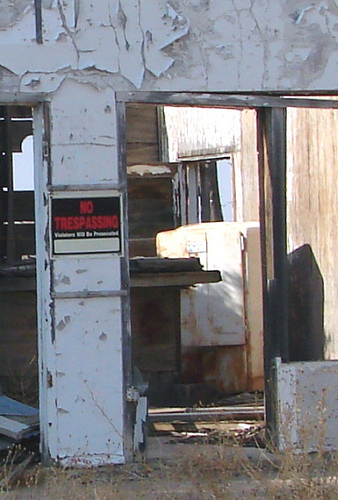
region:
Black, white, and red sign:
[47, 189, 126, 262]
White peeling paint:
[20, 5, 187, 79]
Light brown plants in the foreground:
[15, 407, 321, 499]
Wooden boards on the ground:
[142, 386, 269, 451]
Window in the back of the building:
[168, 138, 244, 244]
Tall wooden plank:
[247, 110, 291, 449]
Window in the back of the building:
[13, 128, 44, 198]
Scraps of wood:
[3, 394, 45, 461]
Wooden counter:
[126, 259, 225, 392]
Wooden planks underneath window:
[2, 190, 43, 267]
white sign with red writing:
[43, 191, 126, 260]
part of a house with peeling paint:
[34, 86, 136, 475]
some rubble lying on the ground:
[141, 382, 267, 444]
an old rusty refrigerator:
[154, 214, 266, 396]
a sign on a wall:
[44, 189, 126, 264]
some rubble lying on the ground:
[0, 391, 42, 454]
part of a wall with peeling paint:
[0, 1, 187, 80]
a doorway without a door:
[0, 83, 56, 470]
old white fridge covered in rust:
[151, 217, 264, 400]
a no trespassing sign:
[46, 191, 126, 260]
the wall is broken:
[108, 373, 203, 457]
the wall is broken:
[125, 386, 183, 492]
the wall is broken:
[120, 380, 183, 437]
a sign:
[47, 158, 170, 331]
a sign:
[50, 163, 125, 294]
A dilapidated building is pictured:
[5, 21, 324, 478]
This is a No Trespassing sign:
[46, 191, 127, 258]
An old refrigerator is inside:
[155, 214, 268, 399]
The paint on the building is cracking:
[55, 3, 193, 87]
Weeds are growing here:
[190, 406, 331, 496]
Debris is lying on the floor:
[151, 387, 265, 444]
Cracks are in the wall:
[207, 8, 286, 81]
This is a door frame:
[110, 87, 281, 452]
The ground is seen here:
[43, 461, 226, 489]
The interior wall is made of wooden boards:
[1, 113, 30, 257]